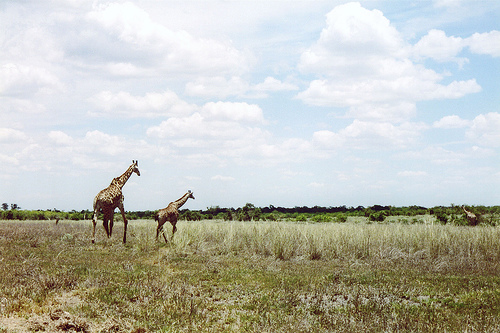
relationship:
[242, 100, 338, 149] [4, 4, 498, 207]
section of sky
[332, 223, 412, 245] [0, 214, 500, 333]
section of grass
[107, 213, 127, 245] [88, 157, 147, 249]
leg of giraffe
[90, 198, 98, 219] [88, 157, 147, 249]
tail of giraffe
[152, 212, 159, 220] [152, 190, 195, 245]
tail of giraffe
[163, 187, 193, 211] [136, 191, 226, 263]
neck of giraffe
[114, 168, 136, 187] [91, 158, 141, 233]
neck of giraffe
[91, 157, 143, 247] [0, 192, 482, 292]
giraffe in plantation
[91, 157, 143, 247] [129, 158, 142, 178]
giraffe has head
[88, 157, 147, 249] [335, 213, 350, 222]
giraffe towards tree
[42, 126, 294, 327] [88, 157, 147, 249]
back of a giraffe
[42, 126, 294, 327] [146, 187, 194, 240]
back of a giraffe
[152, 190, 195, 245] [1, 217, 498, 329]
giraffe on grassy plain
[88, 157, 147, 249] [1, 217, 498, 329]
giraffe on grassy plain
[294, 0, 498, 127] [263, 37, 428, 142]
cloud more than sky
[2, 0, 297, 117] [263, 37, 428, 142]
cloud more than sky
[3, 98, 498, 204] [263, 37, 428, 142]
cloud more than sky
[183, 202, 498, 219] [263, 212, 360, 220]
trees and grass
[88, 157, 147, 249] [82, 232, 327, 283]
giraffe walking on grass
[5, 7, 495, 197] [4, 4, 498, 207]
clouds in sky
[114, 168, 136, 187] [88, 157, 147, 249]
neck of giraffe